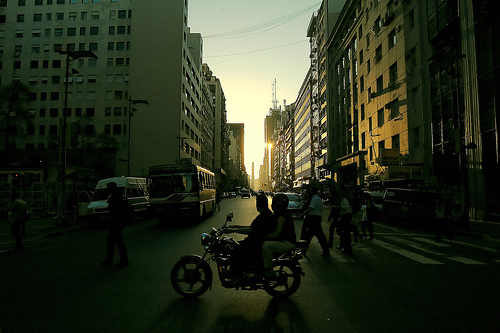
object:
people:
[329, 183, 359, 253]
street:
[225, 181, 258, 212]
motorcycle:
[169, 227, 306, 299]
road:
[126, 300, 247, 331]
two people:
[237, 196, 305, 250]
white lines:
[370, 233, 444, 270]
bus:
[142, 167, 221, 224]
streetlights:
[51, 45, 103, 227]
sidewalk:
[26, 216, 53, 232]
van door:
[71, 192, 96, 218]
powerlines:
[202, 42, 307, 64]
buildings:
[0, 0, 197, 209]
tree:
[1, 75, 42, 142]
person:
[214, 185, 226, 212]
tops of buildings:
[182, 0, 329, 26]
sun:
[244, 143, 271, 155]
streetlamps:
[123, 95, 147, 175]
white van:
[87, 177, 150, 213]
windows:
[73, 72, 87, 88]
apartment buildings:
[270, 105, 303, 190]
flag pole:
[278, 92, 291, 107]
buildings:
[300, 22, 337, 200]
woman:
[362, 190, 381, 241]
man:
[96, 179, 134, 268]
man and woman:
[220, 194, 292, 282]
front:
[146, 165, 211, 216]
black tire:
[168, 255, 210, 299]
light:
[253, 141, 276, 190]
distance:
[244, 149, 272, 194]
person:
[297, 182, 328, 260]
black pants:
[300, 217, 334, 258]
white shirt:
[301, 194, 331, 218]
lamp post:
[437, 52, 475, 229]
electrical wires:
[198, 4, 331, 42]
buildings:
[340, 1, 482, 213]